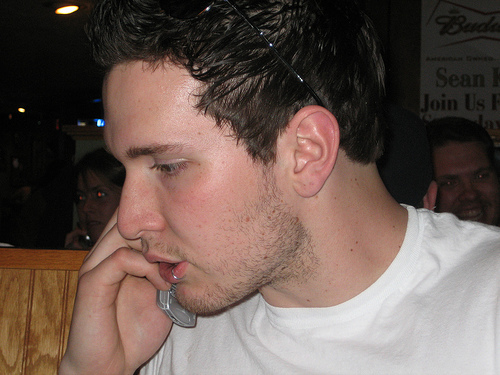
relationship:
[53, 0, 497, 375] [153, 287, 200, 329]
man talking on cellphone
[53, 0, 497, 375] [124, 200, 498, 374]
man wearing shirt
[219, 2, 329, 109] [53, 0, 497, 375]
sunglasses on man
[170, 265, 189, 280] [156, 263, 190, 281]
lip on mans lip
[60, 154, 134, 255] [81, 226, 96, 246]
woman on her cellphone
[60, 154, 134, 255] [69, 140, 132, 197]
woman has brown hair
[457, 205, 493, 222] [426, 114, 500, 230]
smile on man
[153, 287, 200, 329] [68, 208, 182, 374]
cellphone in mans hand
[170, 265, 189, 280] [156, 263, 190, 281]
lip in lip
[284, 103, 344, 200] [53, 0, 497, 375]
ear of man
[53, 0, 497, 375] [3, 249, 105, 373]
man sitting in booth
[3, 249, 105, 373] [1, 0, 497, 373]
booth in restaurant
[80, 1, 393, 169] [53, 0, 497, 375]
hair of man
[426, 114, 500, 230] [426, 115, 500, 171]
man with hair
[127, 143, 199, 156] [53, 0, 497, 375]
eyebrow of man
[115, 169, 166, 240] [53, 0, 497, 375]
nose of man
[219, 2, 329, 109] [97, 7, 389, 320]
sunglasses on head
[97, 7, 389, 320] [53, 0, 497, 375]
head of man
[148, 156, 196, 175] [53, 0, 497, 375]
eye of man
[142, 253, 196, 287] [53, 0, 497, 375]
mouth of man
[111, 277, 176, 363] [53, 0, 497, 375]
palm of man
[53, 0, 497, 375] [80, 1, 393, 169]
man with hair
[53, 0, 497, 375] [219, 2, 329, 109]
man with sunglasses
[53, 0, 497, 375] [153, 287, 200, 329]
man with cellphone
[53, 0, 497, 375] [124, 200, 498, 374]
man wearing a shirt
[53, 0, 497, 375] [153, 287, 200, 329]
man on cellphone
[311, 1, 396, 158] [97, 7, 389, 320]
back of head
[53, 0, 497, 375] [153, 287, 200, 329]
man holding cellphone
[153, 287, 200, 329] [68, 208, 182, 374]
cellphone in hand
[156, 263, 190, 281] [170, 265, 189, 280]
lip with lip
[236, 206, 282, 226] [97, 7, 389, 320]
freckles on head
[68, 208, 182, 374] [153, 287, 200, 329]
hand holding cellphone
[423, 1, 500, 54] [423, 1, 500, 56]
budweiser in a bowtie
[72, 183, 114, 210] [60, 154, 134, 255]
eyes of woman